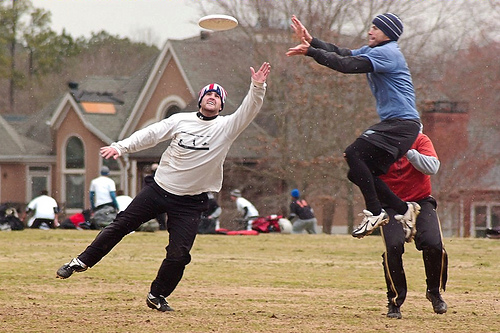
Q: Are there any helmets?
A: No, there are no helmets.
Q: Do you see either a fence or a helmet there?
A: No, there are no helmets or fences.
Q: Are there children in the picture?
A: No, there are no children.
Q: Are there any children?
A: No, there are no children.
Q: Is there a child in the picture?
A: No, there are no children.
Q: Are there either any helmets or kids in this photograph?
A: No, there are no kids or helmets.